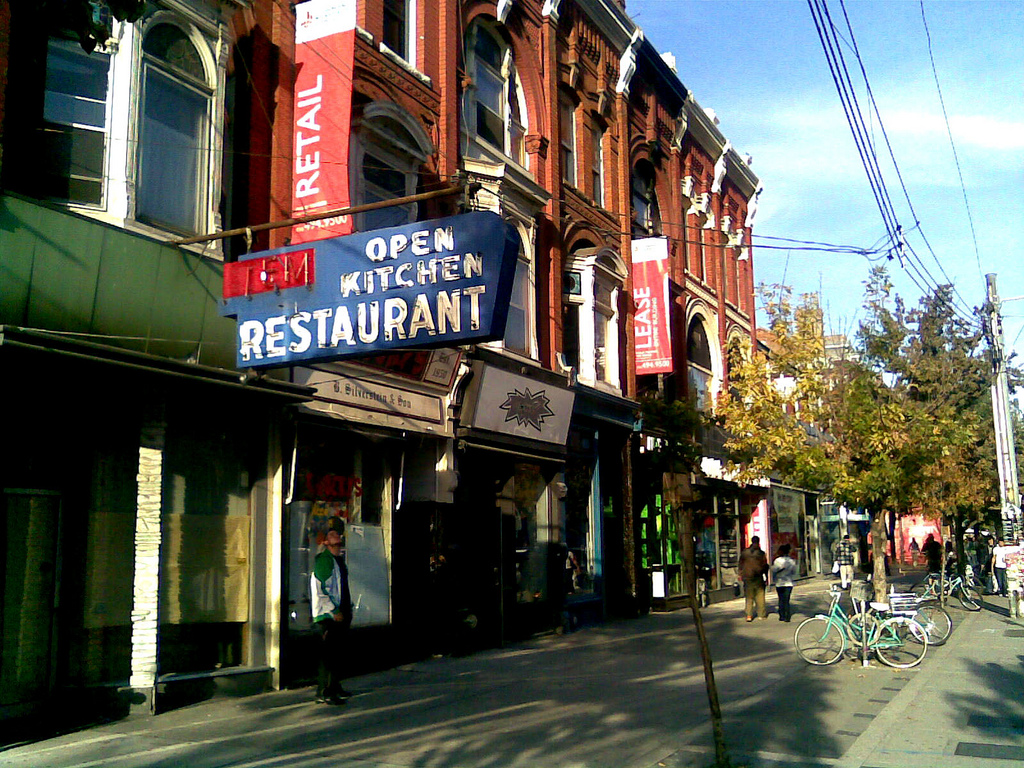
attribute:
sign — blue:
[215, 207, 511, 379]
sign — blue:
[234, 278, 490, 370]